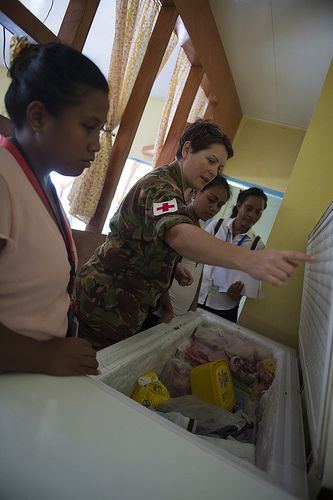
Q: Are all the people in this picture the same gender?
A: Yes, all the people are female.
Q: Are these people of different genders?
A: No, all the people are female.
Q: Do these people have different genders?
A: No, all the people are female.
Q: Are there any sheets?
A: No, there are no sheets.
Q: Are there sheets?
A: No, there are no sheets.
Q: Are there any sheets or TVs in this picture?
A: No, there are no sheets or tvs.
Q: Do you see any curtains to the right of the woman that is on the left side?
A: Yes, there is a curtain to the right of the woman.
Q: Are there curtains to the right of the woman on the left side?
A: Yes, there is a curtain to the right of the woman.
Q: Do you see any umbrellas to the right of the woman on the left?
A: No, there is a curtain to the right of the woman.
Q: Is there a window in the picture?
A: Yes, there is a window.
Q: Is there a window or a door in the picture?
A: Yes, there is a window.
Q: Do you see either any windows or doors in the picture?
A: Yes, there is a window.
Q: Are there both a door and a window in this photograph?
A: Yes, there are both a window and a door.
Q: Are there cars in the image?
A: No, there are no cars.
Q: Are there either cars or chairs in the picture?
A: No, there are no cars or chairs.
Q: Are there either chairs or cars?
A: No, there are no cars or chairs.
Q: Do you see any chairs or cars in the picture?
A: No, there are no cars or chairs.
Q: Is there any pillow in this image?
A: No, there are no pillows.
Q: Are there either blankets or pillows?
A: No, there are no pillows or blankets.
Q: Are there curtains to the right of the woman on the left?
A: Yes, there is a curtain to the right of the woman.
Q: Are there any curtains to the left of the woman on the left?
A: No, the curtain is to the right of the woman.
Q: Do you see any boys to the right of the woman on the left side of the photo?
A: No, there is a curtain to the right of the woman.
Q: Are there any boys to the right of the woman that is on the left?
A: No, there is a curtain to the right of the woman.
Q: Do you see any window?
A: Yes, there is a window.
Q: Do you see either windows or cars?
A: Yes, there is a window.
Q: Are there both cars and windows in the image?
A: No, there is a window but no cars.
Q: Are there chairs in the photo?
A: No, there are no chairs.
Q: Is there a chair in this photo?
A: No, there are no chairs.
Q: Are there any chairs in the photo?
A: No, there are no chairs.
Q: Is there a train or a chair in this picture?
A: No, there are no chairs or trains.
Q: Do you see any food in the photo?
A: Yes, there is food.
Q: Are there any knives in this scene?
A: No, there are no knives.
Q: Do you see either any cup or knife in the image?
A: No, there are no knives or cups.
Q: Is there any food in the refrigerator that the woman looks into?
A: Yes, there is food in the refrigerator.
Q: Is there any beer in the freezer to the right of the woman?
A: No, there is food in the refrigerator.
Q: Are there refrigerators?
A: Yes, there is a refrigerator.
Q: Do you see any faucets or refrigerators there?
A: Yes, there is a refrigerator.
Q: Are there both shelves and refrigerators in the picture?
A: No, there is a refrigerator but no shelves.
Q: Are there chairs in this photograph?
A: No, there are no chairs.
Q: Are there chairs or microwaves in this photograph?
A: No, there are no chairs or microwaves.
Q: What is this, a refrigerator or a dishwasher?
A: This is a refrigerator.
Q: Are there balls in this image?
A: No, there are no balls.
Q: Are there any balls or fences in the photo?
A: No, there are no balls or fences.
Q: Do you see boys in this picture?
A: No, there are no boys.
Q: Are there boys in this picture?
A: No, there are no boys.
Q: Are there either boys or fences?
A: No, there are no boys or fences.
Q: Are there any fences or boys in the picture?
A: No, there are no boys or fences.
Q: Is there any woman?
A: Yes, there is a woman.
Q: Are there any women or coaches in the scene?
A: Yes, there is a woman.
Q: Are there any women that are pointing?
A: Yes, there is a woman that is pointing.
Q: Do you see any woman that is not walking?
A: Yes, there is a woman that is pointing .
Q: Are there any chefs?
A: No, there are no chefs.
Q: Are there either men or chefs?
A: No, there are no chefs or men.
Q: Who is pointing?
A: The woman is pointing.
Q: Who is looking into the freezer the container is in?
A: The woman is looking into the fridge.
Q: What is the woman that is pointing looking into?
A: The woman is looking into the fridge.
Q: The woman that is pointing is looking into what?
A: The woman is looking into the fridge.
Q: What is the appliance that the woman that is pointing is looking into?
A: The appliance is a refrigerator.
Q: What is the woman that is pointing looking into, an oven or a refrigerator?
A: The woman is looking into a refrigerator.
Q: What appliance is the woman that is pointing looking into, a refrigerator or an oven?
A: The woman is looking into a refrigerator.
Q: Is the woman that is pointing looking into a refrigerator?
A: Yes, the woman is looking into a refrigerator.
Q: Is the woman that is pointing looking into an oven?
A: No, the woman is looking into a refrigerator.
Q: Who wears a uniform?
A: The woman wears a uniform.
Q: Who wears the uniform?
A: The woman wears a uniform.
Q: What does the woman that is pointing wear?
A: The woman wears a uniform.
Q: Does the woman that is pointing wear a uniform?
A: Yes, the woman wears a uniform.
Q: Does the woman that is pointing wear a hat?
A: No, the woman wears a uniform.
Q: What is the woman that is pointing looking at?
A: The woman is looking at the freezer.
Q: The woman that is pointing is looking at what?
A: The woman is looking at the freezer.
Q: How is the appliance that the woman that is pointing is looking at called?
A: The appliance is a refrigerator.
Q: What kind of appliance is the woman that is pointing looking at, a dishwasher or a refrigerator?
A: The woman is looking at a refrigerator.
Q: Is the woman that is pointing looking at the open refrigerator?
A: Yes, the woman is looking at the refrigerator.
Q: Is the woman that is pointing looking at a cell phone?
A: No, the woman is looking at the refrigerator.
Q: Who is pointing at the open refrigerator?
A: The woman is pointing at the fridge.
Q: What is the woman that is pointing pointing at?
A: The woman is pointing at the freezer.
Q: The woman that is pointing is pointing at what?
A: The woman is pointing at the freezer.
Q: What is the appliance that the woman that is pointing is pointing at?
A: The appliance is a refrigerator.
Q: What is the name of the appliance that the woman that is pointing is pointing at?
A: The appliance is a refrigerator.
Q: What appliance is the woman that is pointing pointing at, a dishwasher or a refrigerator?
A: The woman is pointing at a refrigerator.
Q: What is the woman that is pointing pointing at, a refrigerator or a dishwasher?
A: The woman is pointing at a refrigerator.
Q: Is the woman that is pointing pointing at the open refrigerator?
A: Yes, the woman is pointing at the refrigerator.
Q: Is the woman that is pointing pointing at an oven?
A: No, the woman is pointing at the refrigerator.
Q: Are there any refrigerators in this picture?
A: Yes, there is a refrigerator.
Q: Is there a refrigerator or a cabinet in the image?
A: Yes, there is a refrigerator.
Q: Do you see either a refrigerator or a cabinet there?
A: Yes, there is a refrigerator.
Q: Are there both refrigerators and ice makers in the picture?
A: No, there is a refrigerator but no ice makers.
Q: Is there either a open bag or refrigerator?
A: Yes, there is an open refrigerator.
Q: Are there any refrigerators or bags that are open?
A: Yes, the refrigerator is open.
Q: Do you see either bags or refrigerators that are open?
A: Yes, the refrigerator is open.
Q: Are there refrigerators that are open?
A: Yes, there is an open refrigerator.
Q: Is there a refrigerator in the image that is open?
A: Yes, there is a refrigerator that is open.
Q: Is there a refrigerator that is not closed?
A: Yes, there is a open refrigerator.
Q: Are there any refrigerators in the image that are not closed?
A: Yes, there is a open refrigerator.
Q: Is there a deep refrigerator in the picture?
A: Yes, there is a deep refrigerator.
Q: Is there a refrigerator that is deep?
A: Yes, there is a refrigerator that is deep.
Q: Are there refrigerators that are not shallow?
A: Yes, there is a deep refrigerator.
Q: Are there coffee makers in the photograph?
A: No, there are no coffee makers.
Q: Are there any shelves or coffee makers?
A: No, there are no coffee makers or shelves.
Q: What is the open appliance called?
A: The appliance is a refrigerator.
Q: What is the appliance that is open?
A: The appliance is a refrigerator.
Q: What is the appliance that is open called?
A: The appliance is a refrigerator.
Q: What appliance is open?
A: The appliance is a refrigerator.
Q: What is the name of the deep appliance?
A: The appliance is a refrigerator.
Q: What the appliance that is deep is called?
A: The appliance is a refrigerator.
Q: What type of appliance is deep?
A: The appliance is a refrigerator.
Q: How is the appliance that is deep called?
A: The appliance is a refrigerator.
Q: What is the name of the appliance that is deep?
A: The appliance is a refrigerator.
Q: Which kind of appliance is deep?
A: The appliance is a refrigerator.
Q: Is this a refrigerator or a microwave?
A: This is a refrigerator.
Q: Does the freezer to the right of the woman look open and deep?
A: Yes, the freezer is open and deep.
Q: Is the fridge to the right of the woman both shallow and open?
A: No, the freezer is open but deep.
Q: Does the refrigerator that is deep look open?
A: Yes, the freezer is open.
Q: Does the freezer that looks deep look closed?
A: No, the fridge is open.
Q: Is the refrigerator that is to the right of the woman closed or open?
A: The freezer is open.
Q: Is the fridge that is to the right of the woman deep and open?
A: Yes, the freezer is deep and open.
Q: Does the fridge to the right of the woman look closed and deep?
A: No, the freezer is deep but open.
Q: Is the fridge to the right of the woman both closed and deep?
A: No, the freezer is deep but open.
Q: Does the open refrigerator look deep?
A: Yes, the refrigerator is deep.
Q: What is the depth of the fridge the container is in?
A: The refrigerator is deep.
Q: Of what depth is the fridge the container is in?
A: The refrigerator is deep.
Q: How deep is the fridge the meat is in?
A: The fridge is deep.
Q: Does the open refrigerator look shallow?
A: No, the fridge is deep.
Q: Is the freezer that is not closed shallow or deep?
A: The fridge is deep.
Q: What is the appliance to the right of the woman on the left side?
A: The appliance is a refrigerator.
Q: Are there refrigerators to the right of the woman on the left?
A: Yes, there is a refrigerator to the right of the woman.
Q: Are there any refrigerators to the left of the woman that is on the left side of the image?
A: No, the refrigerator is to the right of the woman.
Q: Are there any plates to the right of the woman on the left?
A: No, there is a refrigerator to the right of the woman.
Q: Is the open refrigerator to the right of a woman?
A: Yes, the refrigerator is to the right of a woman.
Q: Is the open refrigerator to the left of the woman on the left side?
A: No, the freezer is to the right of the woman.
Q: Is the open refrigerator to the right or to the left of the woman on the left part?
A: The freezer is to the right of the woman.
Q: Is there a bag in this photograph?
A: Yes, there is a bag.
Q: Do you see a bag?
A: Yes, there is a bag.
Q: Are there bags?
A: Yes, there is a bag.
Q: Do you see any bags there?
A: Yes, there is a bag.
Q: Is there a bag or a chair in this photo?
A: Yes, there is a bag.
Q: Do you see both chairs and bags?
A: No, there is a bag but no chairs.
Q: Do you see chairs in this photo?
A: No, there are no chairs.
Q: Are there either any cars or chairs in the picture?
A: No, there are no chairs or cars.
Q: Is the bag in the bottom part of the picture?
A: Yes, the bag is in the bottom of the image.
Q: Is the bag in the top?
A: No, the bag is in the bottom of the image.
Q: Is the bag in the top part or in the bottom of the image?
A: The bag is in the bottom of the image.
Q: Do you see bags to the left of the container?
A: Yes, there is a bag to the left of the container.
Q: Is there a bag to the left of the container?
A: Yes, there is a bag to the left of the container.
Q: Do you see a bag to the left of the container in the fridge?
A: Yes, there is a bag to the left of the container.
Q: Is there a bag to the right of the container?
A: No, the bag is to the left of the container.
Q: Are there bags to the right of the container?
A: No, the bag is to the left of the container.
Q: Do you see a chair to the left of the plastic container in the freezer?
A: No, there is a bag to the left of the container.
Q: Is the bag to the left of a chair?
A: No, the bag is to the left of the container.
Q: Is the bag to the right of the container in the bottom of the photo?
A: No, the bag is to the left of the container.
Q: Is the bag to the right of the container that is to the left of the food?
A: No, the bag is to the left of the container.